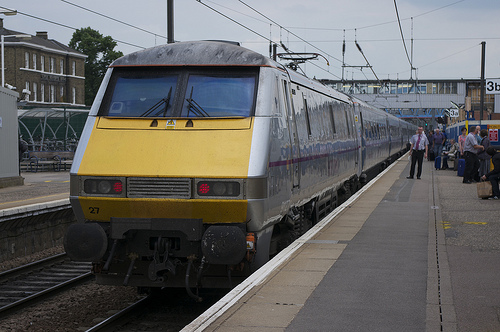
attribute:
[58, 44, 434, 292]
train — commuter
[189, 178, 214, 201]
light — red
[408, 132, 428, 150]
shirt — short sleeved